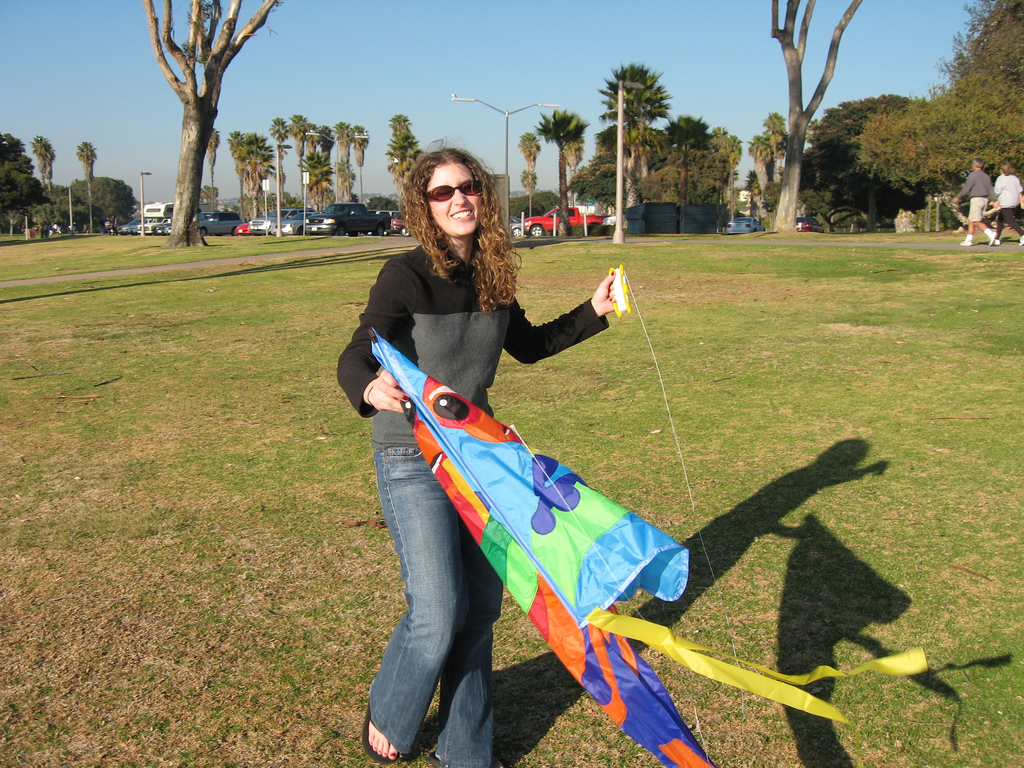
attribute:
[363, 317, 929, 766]
umbrella — bright, graphical print, blue, purple, orange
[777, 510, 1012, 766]
shadow — umbrella, black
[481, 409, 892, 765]
shadow — black, woman, tall, thin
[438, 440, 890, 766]
shadow — thin, tall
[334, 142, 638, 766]
girl — tall, brunette, happy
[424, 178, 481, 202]
glasses — tinted, red